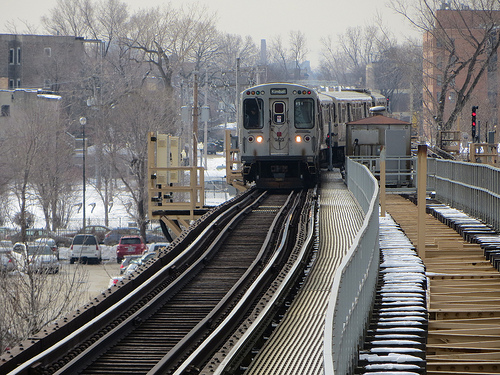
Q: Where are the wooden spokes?
A: Besides train.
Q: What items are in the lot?
A: Train tracks and cars.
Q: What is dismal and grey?
A: Sky.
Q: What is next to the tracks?
A: Railing.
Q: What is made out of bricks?
A: Building.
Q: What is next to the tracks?
A: Leafless tree.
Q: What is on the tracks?
A: Train.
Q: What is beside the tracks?
A: Fence.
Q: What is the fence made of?
A: Metal.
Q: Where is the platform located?
A: Train.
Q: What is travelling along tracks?
A: A train.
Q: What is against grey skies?
A: Trees.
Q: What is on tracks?
A: A grey train.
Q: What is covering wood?
A: White snow.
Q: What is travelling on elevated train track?
A: A train.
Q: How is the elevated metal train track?
A: Long.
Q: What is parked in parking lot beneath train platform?
A: Cars.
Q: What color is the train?
A: Grey.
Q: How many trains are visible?
A: One.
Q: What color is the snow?
A: White.